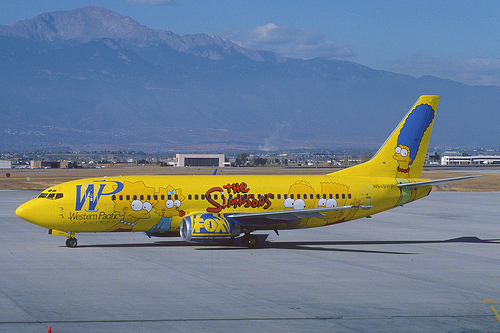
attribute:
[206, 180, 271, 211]
lettering — red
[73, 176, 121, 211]
lettering — blue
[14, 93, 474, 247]
plane — yellow, painted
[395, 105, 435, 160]
paint — blue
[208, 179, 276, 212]
lettering — red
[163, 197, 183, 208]
eyes — white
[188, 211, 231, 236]
logo — Fox network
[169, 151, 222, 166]
building — large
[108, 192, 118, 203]
window — small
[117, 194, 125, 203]
window — small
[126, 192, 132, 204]
window — small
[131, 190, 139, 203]
window — small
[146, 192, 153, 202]
window — small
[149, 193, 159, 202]
window — small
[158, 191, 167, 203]
window — small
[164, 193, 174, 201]
window — small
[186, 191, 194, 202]
window — small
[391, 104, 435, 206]
marge simpson — painted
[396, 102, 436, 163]
hair — long, blue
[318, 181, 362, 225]
bart simpson — waving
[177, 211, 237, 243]
engine — blue, yellow, silver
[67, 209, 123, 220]
western pacific — black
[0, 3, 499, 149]
mountain — blue hued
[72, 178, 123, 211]
logo — WP, large, blue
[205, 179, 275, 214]
logo — The Simpsons, red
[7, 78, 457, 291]
plane — simpsons, yellow, long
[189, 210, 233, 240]
fox — word, yellow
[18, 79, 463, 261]
plane — yellow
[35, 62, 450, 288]
airplane — yellow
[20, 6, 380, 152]
mountain range — distant